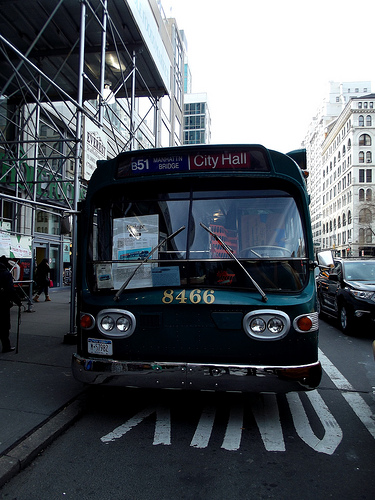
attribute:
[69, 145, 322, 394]
bus — black, shiny, green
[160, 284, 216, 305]
numbers — gold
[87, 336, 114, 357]
plate — blue, white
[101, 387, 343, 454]
letters — white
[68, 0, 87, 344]
pole — steel, metal, large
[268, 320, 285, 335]
headlight — clear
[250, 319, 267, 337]
headlight — clear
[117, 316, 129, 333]
headlight — clear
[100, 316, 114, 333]
headlight — clear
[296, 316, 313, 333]
headlight — red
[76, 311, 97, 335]
headlight — red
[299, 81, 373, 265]
building — grey, glass, tall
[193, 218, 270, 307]
wiper — black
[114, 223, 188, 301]
wiper — black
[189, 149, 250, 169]
sign — red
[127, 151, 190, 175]
sign — blue